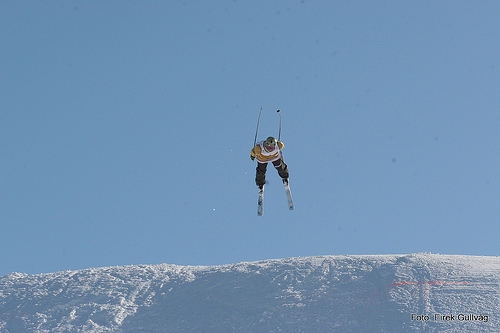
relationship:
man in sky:
[247, 135, 296, 197] [0, 1, 499, 265]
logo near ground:
[405, 304, 495, 326] [2, 253, 500, 330]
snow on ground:
[0, 258, 499, 331] [2, 253, 500, 330]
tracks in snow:
[81, 274, 357, 315] [0, 258, 499, 331]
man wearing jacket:
[247, 135, 296, 197] [251, 145, 282, 164]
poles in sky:
[253, 104, 288, 143] [0, 1, 499, 265]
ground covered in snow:
[2, 253, 500, 330] [0, 258, 499, 331]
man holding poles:
[247, 135, 296, 197] [253, 104, 288, 143]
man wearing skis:
[247, 135, 296, 197] [257, 192, 303, 214]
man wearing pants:
[247, 135, 296, 197] [254, 159, 290, 182]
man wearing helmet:
[247, 135, 296, 197] [262, 135, 279, 147]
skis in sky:
[257, 192, 303, 214] [0, 1, 499, 265]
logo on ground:
[405, 304, 495, 326] [2, 253, 500, 330]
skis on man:
[257, 192, 303, 214] [247, 135, 296, 197]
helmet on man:
[262, 135, 279, 147] [247, 135, 296, 197]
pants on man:
[254, 159, 290, 182] [247, 135, 296, 197]